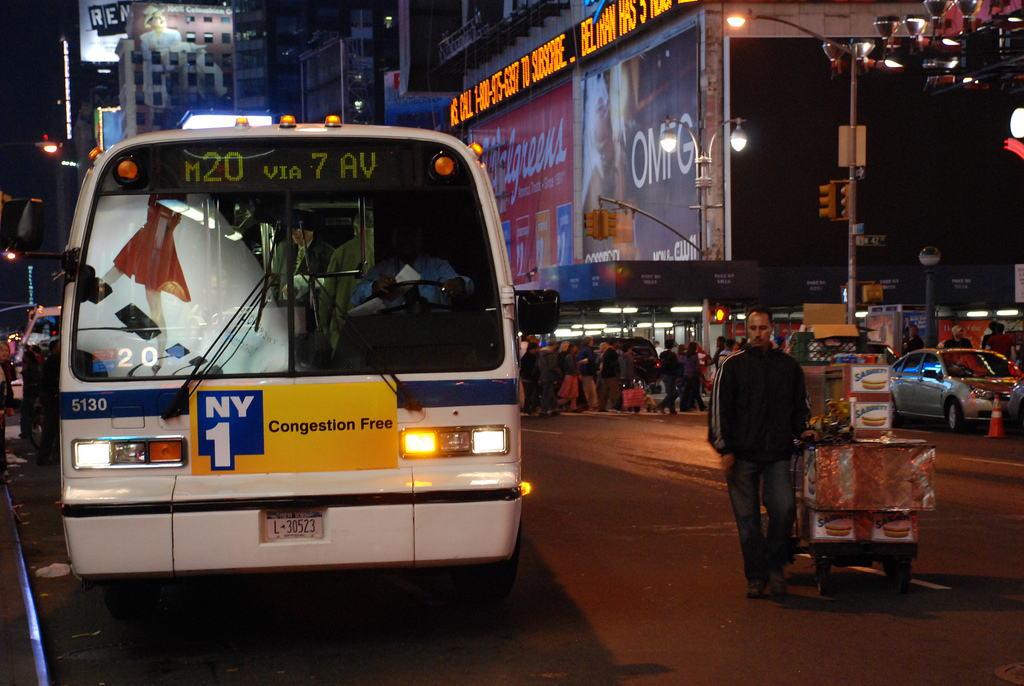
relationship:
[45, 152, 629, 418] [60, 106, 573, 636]
glass of bus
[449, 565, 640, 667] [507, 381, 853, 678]
shadow on road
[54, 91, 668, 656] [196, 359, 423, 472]
bus with sign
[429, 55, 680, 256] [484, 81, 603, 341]
billboard with lettering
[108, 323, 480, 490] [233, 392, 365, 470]
sign with lettering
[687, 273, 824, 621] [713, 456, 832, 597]
man wearing jeans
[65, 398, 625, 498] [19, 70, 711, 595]
headlights on bus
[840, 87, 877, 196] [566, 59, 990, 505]
window on building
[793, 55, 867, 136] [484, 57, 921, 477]
window on building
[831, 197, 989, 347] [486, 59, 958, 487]
window on building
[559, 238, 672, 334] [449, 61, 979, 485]
window on building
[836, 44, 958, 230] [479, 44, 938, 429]
window on building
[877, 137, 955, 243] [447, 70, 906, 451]
window on building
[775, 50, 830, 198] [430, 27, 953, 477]
window on building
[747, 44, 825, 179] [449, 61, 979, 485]
window on building